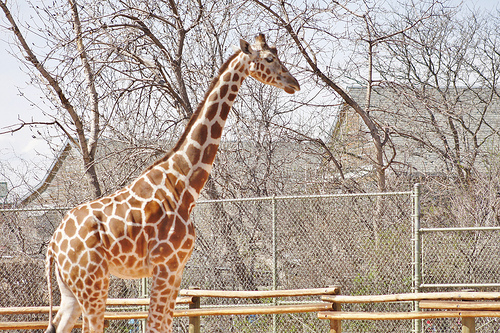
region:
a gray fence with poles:
[311, 225, 383, 269]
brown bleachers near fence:
[347, 290, 477, 300]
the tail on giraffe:
[41, 255, 58, 332]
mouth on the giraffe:
[287, 83, 306, 100]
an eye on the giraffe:
[262, 55, 278, 65]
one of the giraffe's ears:
[256, 31, 272, 51]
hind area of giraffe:
[47, 225, 94, 280]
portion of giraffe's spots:
[122, 209, 181, 246]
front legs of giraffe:
[147, 267, 183, 331]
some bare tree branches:
[70, 42, 151, 103]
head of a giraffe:
[215, 27, 314, 107]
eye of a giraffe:
[260, 52, 278, 67]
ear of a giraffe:
[231, 35, 258, 62]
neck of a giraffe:
[162, 56, 249, 185]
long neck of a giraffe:
[149, 65, 246, 184]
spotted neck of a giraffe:
[152, 66, 244, 182]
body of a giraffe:
[57, 182, 193, 264]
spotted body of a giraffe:
[52, 186, 189, 268]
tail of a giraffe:
[36, 258, 61, 326]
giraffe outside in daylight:
[34, 26, 401, 316]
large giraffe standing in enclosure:
[47, 36, 359, 327]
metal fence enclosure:
[288, 192, 391, 256]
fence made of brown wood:
[193, 287, 351, 332]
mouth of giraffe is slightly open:
[279, 83, 303, 102]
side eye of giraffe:
[256, 50, 276, 73]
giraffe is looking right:
[61, 34, 307, 331]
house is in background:
[341, 78, 498, 239]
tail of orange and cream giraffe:
[23, 247, 60, 331]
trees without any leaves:
[12, 8, 120, 178]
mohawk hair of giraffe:
[163, 142, 181, 158]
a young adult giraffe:
[5, 21, 331, 331]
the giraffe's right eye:
[257, 52, 277, 67]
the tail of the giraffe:
[29, 243, 69, 330]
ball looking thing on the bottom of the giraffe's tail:
[39, 318, 62, 332]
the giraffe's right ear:
[231, 31, 256, 59]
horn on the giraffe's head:
[251, 25, 271, 46]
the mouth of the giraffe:
[281, 70, 309, 102]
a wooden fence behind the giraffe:
[0, 277, 498, 329]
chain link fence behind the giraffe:
[2, 166, 497, 331]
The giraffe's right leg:
[141, 261, 192, 332]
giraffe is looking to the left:
[91, 19, 334, 291]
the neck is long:
[118, 36, 295, 251]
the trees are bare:
[23, 17, 499, 271]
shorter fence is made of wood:
[222, 251, 451, 329]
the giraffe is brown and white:
[87, 25, 317, 325]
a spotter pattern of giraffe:
[67, 29, 324, 331]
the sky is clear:
[1, 45, 51, 121]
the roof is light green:
[345, 57, 445, 194]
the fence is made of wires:
[293, 161, 445, 331]